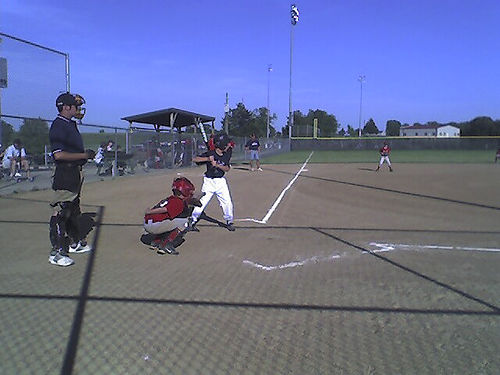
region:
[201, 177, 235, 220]
the pants are white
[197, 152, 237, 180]
the top is black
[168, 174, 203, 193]
the helmet is red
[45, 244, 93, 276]
the shoes are white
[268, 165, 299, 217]
the line is white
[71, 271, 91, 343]
shadow is on the ground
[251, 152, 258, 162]
the shorts are blue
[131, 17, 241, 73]
the sky is cloudless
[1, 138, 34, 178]
the man is sitted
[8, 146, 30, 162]
the shirt is white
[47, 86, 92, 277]
this is a person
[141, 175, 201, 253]
this is a person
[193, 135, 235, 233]
this is a person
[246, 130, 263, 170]
this is a person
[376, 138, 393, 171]
this is a person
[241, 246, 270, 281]
this is a person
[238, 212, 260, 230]
this is a person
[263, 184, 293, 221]
this is a person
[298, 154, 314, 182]
this is a person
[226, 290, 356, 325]
this is a person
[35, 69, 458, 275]
people on the field playing baseball.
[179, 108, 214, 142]
The boy is holding a bat.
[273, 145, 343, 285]
White lines in the field.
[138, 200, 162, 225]
Boy hand is behind his back.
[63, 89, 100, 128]
Umpire is wearing a face mask.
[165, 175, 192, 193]
The boy is wearing a red helmet.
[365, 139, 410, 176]
A player in the field.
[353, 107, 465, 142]
Buildings behind the fence.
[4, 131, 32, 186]
A person sitting on the bleachers.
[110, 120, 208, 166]
People standing behind the fence.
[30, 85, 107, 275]
person standing on a baseball field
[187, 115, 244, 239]
person standing on a baseball field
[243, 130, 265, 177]
person standing on a baseball field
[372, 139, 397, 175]
person standing on a baseball field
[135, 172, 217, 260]
person standing on a baseball field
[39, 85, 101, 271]
person wearing a black mask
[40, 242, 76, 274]
white and black shoe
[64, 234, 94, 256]
white and black shoe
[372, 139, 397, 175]
person wearing a baseball uniform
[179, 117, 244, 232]
person wearing a baseball uniform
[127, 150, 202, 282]
this is a person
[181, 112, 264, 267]
this is a person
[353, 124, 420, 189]
this is a person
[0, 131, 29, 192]
this is a person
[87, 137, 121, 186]
this is a person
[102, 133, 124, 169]
this is a person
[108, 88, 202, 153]
this is a shade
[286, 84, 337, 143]
this is a tree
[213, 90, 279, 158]
this is a tree